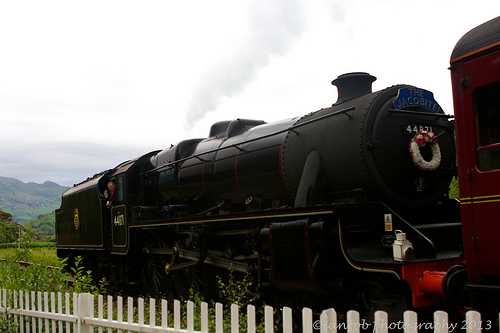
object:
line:
[128, 210, 334, 228]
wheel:
[261, 237, 343, 329]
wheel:
[167, 251, 224, 307]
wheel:
[131, 238, 175, 299]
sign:
[73, 208, 80, 230]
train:
[53, 13, 500, 319]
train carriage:
[448, 15, 500, 299]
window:
[469, 80, 500, 173]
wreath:
[409, 130, 442, 171]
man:
[105, 181, 118, 208]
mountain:
[0, 172, 71, 231]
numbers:
[406, 125, 412, 133]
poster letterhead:
[391, 86, 440, 113]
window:
[116, 176, 124, 202]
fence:
[0, 286, 500, 333]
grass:
[0, 243, 282, 330]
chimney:
[329, 72, 377, 106]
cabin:
[52, 149, 159, 257]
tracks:
[0, 260, 114, 295]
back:
[53, 168, 112, 283]